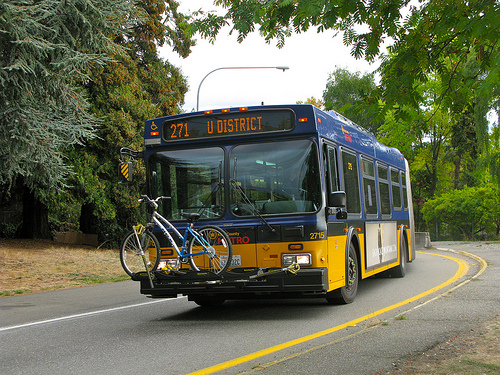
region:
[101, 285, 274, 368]
The pavement is gray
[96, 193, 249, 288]
The bike is on the bus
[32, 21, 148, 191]
The tree is green and tall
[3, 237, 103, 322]
The dirt is brown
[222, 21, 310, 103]
The street light is off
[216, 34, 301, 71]
The sky is white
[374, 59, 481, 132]
The leaves are green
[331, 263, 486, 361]
The road has lines on it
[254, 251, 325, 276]
The bus light is on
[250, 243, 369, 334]
The bus is yellow on the bottom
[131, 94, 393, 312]
the bus on the street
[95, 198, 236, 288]
the bicycle on the bus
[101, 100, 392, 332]
the bus is gold and blue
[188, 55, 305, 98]
the street light above the bus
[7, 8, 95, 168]
pine trees beside the bus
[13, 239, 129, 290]
the grass beside the street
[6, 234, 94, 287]
the grass is dry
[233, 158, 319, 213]
the windshield of the bus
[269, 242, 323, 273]
head light of the bus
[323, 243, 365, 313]
front tire of bus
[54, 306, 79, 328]
white line on the road.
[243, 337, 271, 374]
yellow line on the road.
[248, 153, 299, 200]
windshield on the bus.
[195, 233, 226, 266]
tire on the bicycle.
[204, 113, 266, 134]
words on the sign.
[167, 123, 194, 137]
number on the sign.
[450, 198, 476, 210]
leaves on the tree.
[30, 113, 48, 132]
pine needles on tree.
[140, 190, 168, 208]
handlebars on the bicycle.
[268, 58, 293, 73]
light on the pole.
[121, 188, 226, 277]
bike on the front of the bus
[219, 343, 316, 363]
yellow line painted on the road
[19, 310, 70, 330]
white line painted on the road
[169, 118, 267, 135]
led sign on front of the bus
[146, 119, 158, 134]
handicap symbol on front of the bus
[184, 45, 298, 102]
street light over the road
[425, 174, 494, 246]
bushes behind the bus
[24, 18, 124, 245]
trees on the side of the road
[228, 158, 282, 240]
windshield wiper on the bus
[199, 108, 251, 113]
lights on the top of the bus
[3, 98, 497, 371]
A bus on the road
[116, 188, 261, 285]
Bicycle on front of bus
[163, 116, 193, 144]
The number 271 on the bus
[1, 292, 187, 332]
White line on the road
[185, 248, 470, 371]
Curved yellow line on road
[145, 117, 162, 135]
Handicap symbol on bus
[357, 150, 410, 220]
Windows on side of bus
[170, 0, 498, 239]
Green leaves on trees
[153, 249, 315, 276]
Headlights on the bus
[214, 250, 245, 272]
A white license plate